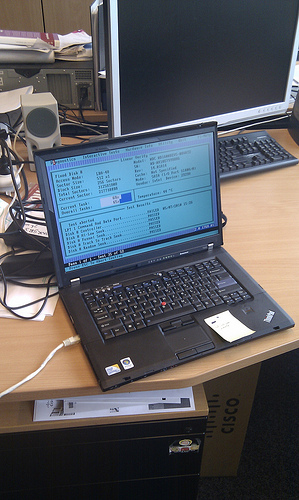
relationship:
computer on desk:
[40, 156, 232, 344] [0, 130, 297, 412]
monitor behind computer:
[97, 5, 297, 100] [31, 119, 294, 394]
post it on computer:
[191, 302, 250, 357] [40, 156, 232, 344]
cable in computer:
[11, 332, 92, 387] [40, 156, 232, 344]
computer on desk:
[31, 119, 294, 394] [23, 327, 287, 411]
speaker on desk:
[25, 73, 109, 132] [23, 327, 287, 411]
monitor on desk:
[97, 5, 297, 100] [23, 327, 287, 411]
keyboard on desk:
[113, 277, 230, 327] [23, 327, 287, 411]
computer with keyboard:
[31, 119, 294, 394] [113, 277, 230, 327]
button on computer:
[162, 321, 235, 335] [31, 119, 294, 394]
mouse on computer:
[156, 327, 255, 375] [31, 119, 294, 394]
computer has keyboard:
[31, 119, 294, 394] [113, 277, 230, 327]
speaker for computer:
[25, 73, 109, 132] [40, 156, 232, 344]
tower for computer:
[76, 2, 113, 117] [40, 156, 232, 344]